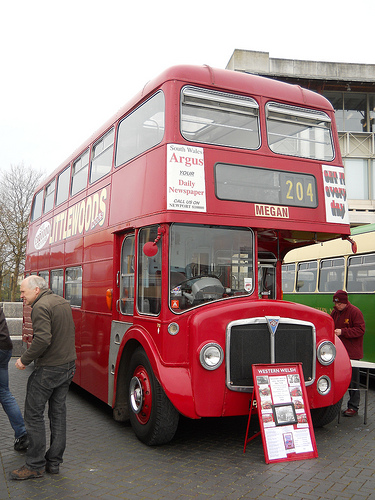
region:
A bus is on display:
[20, 60, 353, 447]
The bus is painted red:
[20, 62, 358, 447]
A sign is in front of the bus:
[243, 361, 320, 464]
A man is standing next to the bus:
[7, 273, 76, 481]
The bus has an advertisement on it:
[164, 141, 207, 213]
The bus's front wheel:
[124, 342, 181, 447]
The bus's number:
[283, 176, 316, 203]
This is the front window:
[168, 221, 256, 314]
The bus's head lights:
[195, 339, 337, 370]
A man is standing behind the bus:
[328, 289, 366, 417]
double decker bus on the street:
[26, 75, 349, 460]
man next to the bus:
[16, 254, 81, 485]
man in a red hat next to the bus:
[328, 279, 367, 359]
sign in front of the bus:
[238, 357, 332, 477]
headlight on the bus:
[197, 331, 221, 378]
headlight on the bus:
[315, 334, 344, 372]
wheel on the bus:
[118, 346, 172, 459]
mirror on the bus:
[140, 221, 167, 264]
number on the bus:
[280, 175, 320, 210]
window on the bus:
[60, 258, 89, 314]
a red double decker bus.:
[19, 76, 360, 464]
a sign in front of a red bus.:
[234, 356, 324, 470]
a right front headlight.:
[195, 324, 240, 378]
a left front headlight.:
[311, 332, 343, 370]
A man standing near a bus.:
[2, 272, 86, 490]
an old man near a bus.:
[5, 257, 86, 487]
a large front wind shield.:
[167, 227, 270, 333]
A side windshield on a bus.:
[112, 235, 139, 328]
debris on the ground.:
[71, 456, 103, 495]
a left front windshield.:
[318, 343, 341, 363]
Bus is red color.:
[27, 148, 268, 354]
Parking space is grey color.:
[135, 435, 256, 496]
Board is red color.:
[248, 364, 321, 471]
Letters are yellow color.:
[27, 197, 122, 244]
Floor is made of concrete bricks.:
[175, 456, 312, 491]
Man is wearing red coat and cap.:
[325, 287, 367, 347]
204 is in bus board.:
[284, 176, 353, 233]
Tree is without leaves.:
[5, 182, 37, 265]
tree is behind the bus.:
[6, 171, 46, 314]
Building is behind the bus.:
[232, 48, 371, 213]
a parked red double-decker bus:
[24, 63, 351, 449]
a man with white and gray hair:
[18, 272, 48, 305]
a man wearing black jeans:
[24, 364, 78, 463]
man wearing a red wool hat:
[332, 290, 348, 303]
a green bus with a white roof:
[282, 231, 374, 366]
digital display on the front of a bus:
[214, 161, 319, 209]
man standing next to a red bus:
[14, 273, 78, 483]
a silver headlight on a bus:
[199, 341, 224, 369]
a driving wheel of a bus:
[168, 273, 224, 304]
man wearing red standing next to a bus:
[330, 290, 364, 417]